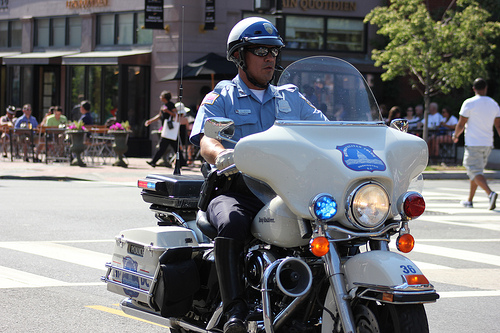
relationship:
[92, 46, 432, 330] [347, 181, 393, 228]
motorcycle has light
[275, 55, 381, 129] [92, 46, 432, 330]
windshield on motorcycle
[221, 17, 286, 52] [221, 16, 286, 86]
helmet on head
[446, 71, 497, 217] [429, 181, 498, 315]
pedestrian crossing white lines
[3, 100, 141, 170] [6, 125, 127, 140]
people sitting tables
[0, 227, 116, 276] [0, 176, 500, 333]
line on ground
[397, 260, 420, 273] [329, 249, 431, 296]
number 36 on bumper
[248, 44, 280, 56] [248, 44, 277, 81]
goggles on face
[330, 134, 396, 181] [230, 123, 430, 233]
shield on hood